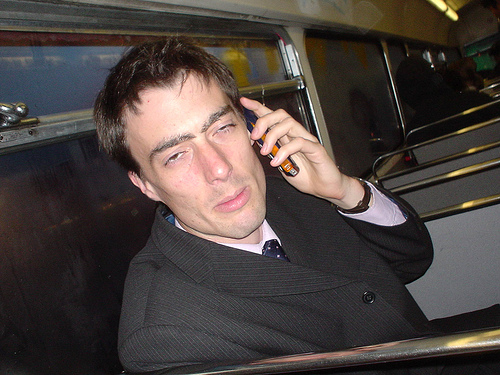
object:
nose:
[190, 139, 234, 184]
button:
[362, 291, 376, 305]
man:
[90, 37, 434, 375]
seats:
[405, 101, 500, 165]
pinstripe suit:
[116, 176, 435, 375]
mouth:
[211, 184, 251, 214]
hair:
[91, 35, 245, 179]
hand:
[239, 95, 343, 199]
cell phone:
[243, 111, 300, 178]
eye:
[211, 121, 239, 137]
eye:
[163, 149, 191, 168]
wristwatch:
[336, 171, 372, 214]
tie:
[262, 238, 292, 263]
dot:
[276, 254, 280, 258]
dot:
[267, 246, 272, 250]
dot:
[275, 245, 279, 249]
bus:
[0, 0, 500, 375]